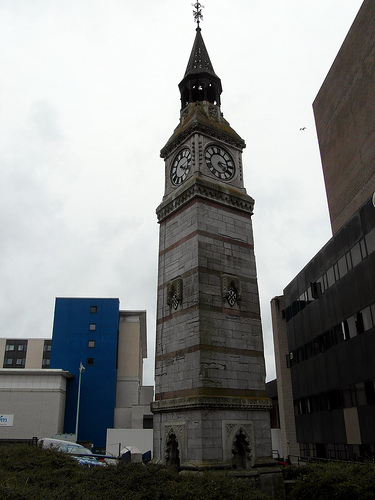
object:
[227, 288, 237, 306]
shield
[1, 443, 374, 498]
ground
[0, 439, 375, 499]
grass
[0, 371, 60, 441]
wall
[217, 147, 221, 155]
roman numeral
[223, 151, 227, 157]
roman numeral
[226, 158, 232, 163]
roman numeral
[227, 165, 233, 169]
roman numeral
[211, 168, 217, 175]
roman numeral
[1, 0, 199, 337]
clouds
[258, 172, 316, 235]
clouds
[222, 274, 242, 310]
window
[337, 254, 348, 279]
window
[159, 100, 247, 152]
roof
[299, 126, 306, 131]
bird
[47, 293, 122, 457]
wall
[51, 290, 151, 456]
building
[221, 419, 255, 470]
archway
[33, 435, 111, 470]
vehicle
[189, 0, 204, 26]
weather vane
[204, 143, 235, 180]
clock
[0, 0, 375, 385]
overcast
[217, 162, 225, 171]
hands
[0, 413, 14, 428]
sign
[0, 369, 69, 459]
building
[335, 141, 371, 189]
panel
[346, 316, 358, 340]
windows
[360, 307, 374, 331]
windows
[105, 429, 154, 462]
wall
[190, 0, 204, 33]
point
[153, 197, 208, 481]
wall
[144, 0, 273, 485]
building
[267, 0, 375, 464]
building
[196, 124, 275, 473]
wall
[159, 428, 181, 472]
archway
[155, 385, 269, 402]
stripe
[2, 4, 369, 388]
sky